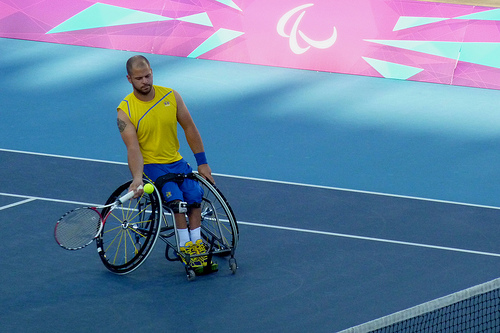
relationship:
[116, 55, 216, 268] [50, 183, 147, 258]
man holding racket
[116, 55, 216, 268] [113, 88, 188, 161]
man wearing shirt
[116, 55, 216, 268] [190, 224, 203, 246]
man wearing sock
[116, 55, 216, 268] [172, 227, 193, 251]
man wearing sock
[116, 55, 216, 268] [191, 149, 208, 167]
man wearing wristband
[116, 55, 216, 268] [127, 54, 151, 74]
man has hair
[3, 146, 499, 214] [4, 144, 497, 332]
line on tennis court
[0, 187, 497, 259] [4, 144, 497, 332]
line on tennis court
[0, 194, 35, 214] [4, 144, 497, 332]
line on tennis court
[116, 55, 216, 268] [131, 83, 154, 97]
man has beard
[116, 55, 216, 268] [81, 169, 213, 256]
man sitting in wheelchair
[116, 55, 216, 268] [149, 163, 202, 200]
man wearing blue shorts